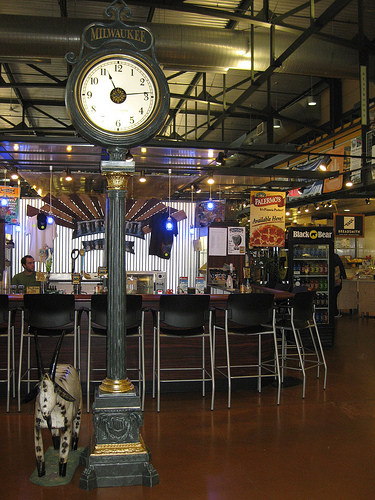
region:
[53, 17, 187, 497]
black and gold clock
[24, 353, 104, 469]
white and black goat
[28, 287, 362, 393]
black and silver stools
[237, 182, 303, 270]
yellow pizza sign hanging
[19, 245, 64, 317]
man standing behind bar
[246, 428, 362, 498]
dark brown tiled floor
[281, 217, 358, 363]
cooler for wine coolers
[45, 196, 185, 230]
tan and brown logo sign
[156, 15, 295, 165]
silver beams on ceiling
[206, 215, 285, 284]
bar menu on wall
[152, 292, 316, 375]
metal bar stools with black cushions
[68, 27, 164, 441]
a clock on a tall pole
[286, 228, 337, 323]
a cooler full of drings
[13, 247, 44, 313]
a man behind a bar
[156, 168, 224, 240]
lights hanging from the cieling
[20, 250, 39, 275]
a man with dark hair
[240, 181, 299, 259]
a sign for pizza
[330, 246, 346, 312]
a person standing at a counter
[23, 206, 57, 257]
a white shirt hanging from the cieling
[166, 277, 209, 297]
menus sitting on a bar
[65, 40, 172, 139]
This is a clock.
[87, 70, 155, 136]
The clock is white and black.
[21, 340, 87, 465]
This looks like a goat.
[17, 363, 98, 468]
The goat is gray and black.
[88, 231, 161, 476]
The lamp post is gold and green.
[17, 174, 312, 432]
This is in a bar.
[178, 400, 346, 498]
The ground here is brown.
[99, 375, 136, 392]
This metal is golden.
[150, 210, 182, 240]
The light is blue.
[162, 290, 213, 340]
The chair is black.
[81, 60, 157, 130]
white face of the clock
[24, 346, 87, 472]
a white and black sculpture of a goat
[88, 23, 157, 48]
brass lettering on a black clock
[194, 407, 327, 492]
shiny brown floors of the bar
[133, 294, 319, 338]
several chairs placed around the bar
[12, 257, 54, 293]
a man in a green shirt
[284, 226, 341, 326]
a cooler filled with drinks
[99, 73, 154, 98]
black hands of the clock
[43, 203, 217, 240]
blue lights hanging over the bar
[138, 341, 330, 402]
metal legs of the bar chair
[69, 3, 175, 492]
Old black decorative Milwaukee clock post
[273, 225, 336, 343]
Black Bear cooler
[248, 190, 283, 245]
Advertisement sign for pizza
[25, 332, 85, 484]
Decorative long horned goat.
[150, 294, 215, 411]
Black very tall legged chair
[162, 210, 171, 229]
Decorative blue light.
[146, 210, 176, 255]
Black shirt on a wall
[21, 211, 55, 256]
White shirt hanging from the wall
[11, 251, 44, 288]
Green shirted man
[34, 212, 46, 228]
Black cap